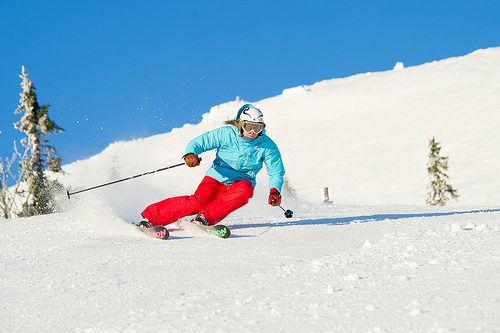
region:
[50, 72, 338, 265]
woman is skiing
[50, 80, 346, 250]
skier wears read pants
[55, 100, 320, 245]
skier holds black poles in the hands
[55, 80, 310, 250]
skier wears blue jacket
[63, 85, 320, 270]
skier wears white helmet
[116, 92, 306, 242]
skier wears goggles around the eyes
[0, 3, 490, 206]
sunny clear sky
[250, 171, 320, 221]
one red and black glove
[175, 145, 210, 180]
one brown glove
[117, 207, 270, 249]
black skis with neon pink and green underneath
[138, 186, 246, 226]
the red pants on a skier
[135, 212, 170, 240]
a black and pink ski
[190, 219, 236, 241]
a black and green ski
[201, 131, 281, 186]
a blue coat on a woman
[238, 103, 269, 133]
a white and black helmet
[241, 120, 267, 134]
white goggles on a skier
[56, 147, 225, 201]
a black ski pole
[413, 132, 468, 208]
a small pine tree in snow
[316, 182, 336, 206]
a marker sticking up in the snow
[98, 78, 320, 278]
a woman skiing in the snow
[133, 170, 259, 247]
Bright red snow sporting pants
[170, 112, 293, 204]
Light blue puffy ski jacket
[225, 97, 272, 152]
White helmet with black swirled patterns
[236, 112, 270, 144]
White and yellow half face goggles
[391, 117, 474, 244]
Snow covered pine tree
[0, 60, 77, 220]
Scraggly small pine tree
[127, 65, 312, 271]
Woman with ski poles downhill skiing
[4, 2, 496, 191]
Cloudless blue midday sky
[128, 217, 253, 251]
Black skis with neon green and pink writing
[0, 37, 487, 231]
Snow covered downhill ski slope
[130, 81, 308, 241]
a skier skiing down a slope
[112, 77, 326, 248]
a skier wearing a blue jacket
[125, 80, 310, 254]
a skier wearing red pants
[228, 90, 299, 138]
a white helmet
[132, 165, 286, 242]
red pants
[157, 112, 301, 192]
blue jacket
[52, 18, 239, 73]
a clear blue sky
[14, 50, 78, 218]
a tree covered in snow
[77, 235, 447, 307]
the ground filled with snow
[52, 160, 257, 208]
a ski pole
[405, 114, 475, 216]
a snow covered tree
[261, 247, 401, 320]
portion of the snow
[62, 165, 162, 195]
part of black ski pole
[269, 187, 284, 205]
hand in the mitten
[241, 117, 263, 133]
sunglasses on ladies face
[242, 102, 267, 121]
helmet on woman's head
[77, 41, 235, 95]
portion of the sky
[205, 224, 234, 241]
bottom part of the ski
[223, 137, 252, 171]
portion of blue jacket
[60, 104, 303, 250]
skier coming down slopes